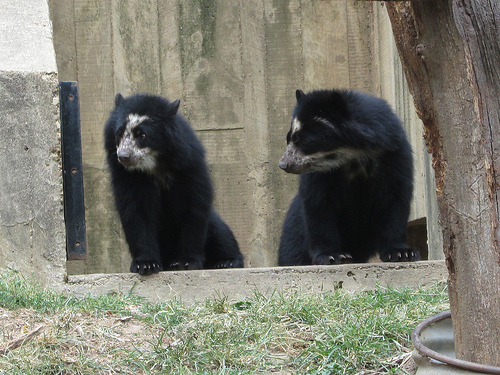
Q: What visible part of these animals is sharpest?
A: The claws.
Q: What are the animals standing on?
A: Cement slab.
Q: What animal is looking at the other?
A: The one on the right.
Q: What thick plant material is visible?
A: A tree trunk.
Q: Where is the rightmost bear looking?
A: To the left.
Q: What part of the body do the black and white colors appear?
A: The face.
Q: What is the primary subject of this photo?
A: The bears.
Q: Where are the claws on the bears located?
A: The paws.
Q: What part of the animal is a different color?
A: It's face.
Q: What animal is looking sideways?
A: The one on the right.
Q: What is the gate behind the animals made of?
A: Wood.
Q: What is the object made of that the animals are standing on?
A: Cement.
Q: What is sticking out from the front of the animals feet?
A: Claws.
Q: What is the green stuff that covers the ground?
A: Grass.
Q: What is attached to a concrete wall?
A: A pillar.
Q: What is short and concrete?
A: A wall.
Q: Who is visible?
A: An animal.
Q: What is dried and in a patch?
A: Grass.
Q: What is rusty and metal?
A: A hinge.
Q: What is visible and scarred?
A: A tree trunk.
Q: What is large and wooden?
A: A door.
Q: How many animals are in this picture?
A: Two.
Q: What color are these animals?
A: Black.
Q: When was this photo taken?
A: Outside, during the daytime.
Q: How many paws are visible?
A: Four.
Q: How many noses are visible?
A: Two.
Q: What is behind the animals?
A: A wooden wall.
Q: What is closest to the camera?
A: A trunk of a tree.